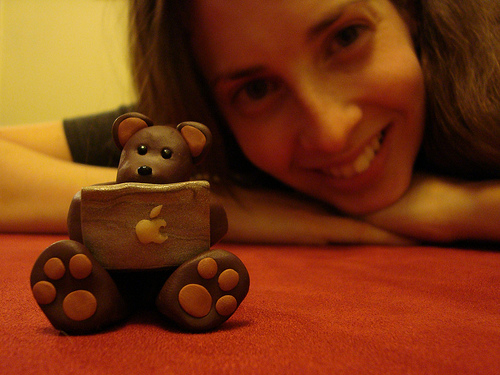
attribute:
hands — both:
[253, 187, 427, 248]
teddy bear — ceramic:
[24, 109, 254, 336]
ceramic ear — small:
[109, 109, 151, 146]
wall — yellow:
[0, 4, 124, 111]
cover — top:
[60, 185, 227, 274]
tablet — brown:
[78, 176, 213, 268]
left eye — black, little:
[242, 76, 270, 101]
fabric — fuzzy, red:
[1, 230, 497, 373]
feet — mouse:
[27, 239, 119, 335]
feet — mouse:
[156, 245, 251, 335]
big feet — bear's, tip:
[45, 238, 78, 259]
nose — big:
[278, 59, 363, 155]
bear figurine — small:
[29, 113, 251, 335]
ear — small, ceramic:
[175, 120, 212, 155]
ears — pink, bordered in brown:
[114, 111, 210, 156]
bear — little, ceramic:
[23, 108, 258, 343]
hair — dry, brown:
[429, 7, 499, 124]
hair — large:
[126, 4, 496, 160]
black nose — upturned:
[136, 163, 152, 178]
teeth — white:
[306, 142, 383, 184]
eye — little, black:
[325, 20, 372, 60]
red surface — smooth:
[2, 232, 499, 369]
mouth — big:
[297, 105, 405, 210]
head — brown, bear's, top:
[107, 105, 217, 187]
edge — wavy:
[67, 167, 228, 203]